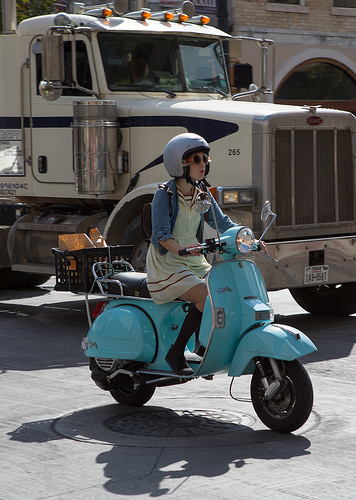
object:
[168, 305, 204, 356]
socks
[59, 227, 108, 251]
paper bag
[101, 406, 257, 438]
manhole cover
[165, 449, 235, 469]
ground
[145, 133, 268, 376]
girl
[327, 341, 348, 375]
ground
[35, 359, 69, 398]
ground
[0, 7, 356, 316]
truck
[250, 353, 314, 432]
tire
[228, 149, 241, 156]
numbers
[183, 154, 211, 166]
sunglasses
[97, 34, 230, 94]
windshield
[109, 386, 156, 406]
tire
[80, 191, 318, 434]
bike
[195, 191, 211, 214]
mirror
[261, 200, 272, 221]
mirror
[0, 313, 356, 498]
concrete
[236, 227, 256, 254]
headlight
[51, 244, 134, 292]
basket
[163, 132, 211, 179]
helmet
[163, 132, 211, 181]
head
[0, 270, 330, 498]
road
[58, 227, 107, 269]
items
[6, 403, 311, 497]
shadow